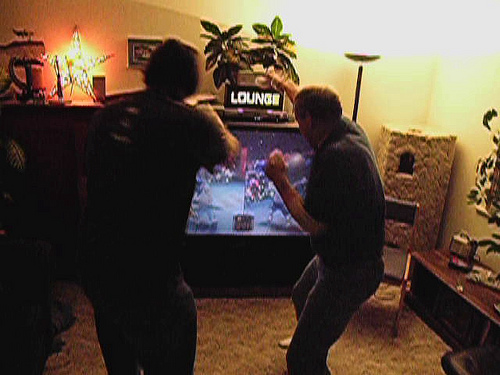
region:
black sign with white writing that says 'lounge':
[219, 79, 287, 116]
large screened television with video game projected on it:
[171, 114, 338, 301]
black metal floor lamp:
[339, 48, 384, 128]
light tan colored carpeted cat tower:
[370, 116, 462, 267]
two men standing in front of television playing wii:
[72, 28, 392, 373]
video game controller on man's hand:
[244, 59, 294, 102]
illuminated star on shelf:
[32, 17, 122, 108]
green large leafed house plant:
[188, 12, 304, 117]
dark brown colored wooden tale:
[382, 232, 498, 362]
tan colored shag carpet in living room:
[16, 268, 496, 374]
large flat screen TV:
[185, 116, 316, 246]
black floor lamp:
[342, 49, 380, 124]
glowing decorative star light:
[39, 25, 115, 102]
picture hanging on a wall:
[121, 34, 164, 68]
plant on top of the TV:
[198, 17, 297, 90]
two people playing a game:
[82, 41, 384, 372]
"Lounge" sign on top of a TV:
[223, 83, 285, 111]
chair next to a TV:
[381, 191, 421, 336]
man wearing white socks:
[275, 334, 293, 347]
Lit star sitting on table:
[33, 19, 115, 104]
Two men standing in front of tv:
[81, 35, 386, 372]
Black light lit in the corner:
[343, 49, 382, 122]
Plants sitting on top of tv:
[198, 15, 300, 90]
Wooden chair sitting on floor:
[360, 193, 419, 338]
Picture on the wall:
[126, 35, 166, 67]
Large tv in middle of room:
[180, 116, 325, 296]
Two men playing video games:
[80, 35, 386, 370]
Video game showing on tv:
[181, 120, 318, 235]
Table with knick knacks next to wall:
[403, 228, 498, 372]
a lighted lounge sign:
[216, 80, 287, 112]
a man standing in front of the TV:
[71, 33, 242, 374]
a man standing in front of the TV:
[261, 60, 387, 373]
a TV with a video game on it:
[181, 120, 322, 238]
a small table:
[392, 249, 498, 340]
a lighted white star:
[41, 23, 106, 105]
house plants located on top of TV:
[196, 10, 302, 105]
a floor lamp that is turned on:
[336, 47, 381, 124]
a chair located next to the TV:
[376, 190, 418, 340]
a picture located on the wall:
[124, 31, 164, 72]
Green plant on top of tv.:
[207, 28, 309, 74]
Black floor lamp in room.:
[336, 42, 384, 114]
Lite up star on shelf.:
[38, 38, 115, 113]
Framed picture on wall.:
[118, 25, 180, 95]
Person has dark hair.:
[139, 33, 203, 115]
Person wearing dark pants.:
[105, 300, 205, 344]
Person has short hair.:
[303, 81, 337, 122]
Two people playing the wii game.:
[104, 65, 396, 332]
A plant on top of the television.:
[197, 28, 305, 94]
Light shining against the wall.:
[40, 30, 117, 100]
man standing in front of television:
[243, 61, 389, 373]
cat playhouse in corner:
[368, 116, 459, 298]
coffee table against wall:
[402, 237, 499, 369]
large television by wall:
[155, 90, 346, 299]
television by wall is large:
[157, 91, 344, 298]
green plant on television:
[197, 11, 302, 111]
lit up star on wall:
[36, 25, 114, 104]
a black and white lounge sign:
[223, 84, 286, 109]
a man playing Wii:
[77, 36, 243, 372]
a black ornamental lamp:
[344, 46, 379, 122]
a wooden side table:
[389, 241, 499, 367]